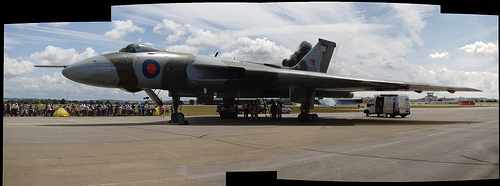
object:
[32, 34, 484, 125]
jet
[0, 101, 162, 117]
people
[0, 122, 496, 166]
runway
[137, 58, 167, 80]
bullseye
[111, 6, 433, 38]
sky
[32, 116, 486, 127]
shadow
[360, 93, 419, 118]
van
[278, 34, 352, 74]
tail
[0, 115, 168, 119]
fence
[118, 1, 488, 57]
clouds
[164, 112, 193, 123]
wheels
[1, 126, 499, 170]
cement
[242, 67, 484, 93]
wing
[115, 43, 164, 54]
cockpit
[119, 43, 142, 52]
window